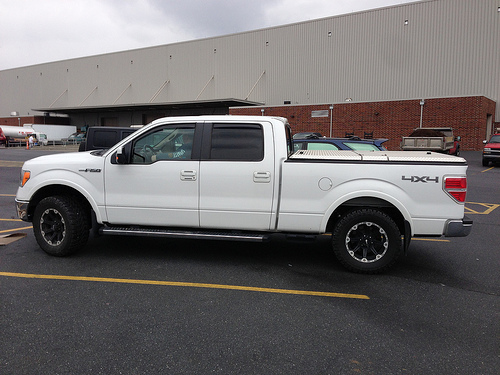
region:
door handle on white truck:
[173, 167, 204, 187]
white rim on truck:
[343, 220, 385, 263]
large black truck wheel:
[323, 203, 425, 293]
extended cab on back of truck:
[262, 107, 467, 189]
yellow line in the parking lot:
[62, 262, 403, 326]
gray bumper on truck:
[447, 215, 485, 242]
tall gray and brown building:
[175, 45, 407, 120]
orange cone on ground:
[21, 135, 30, 150]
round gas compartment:
[311, 173, 336, 195]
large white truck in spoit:
[24, 115, 465, 265]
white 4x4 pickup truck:
[1, 105, 483, 295]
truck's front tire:
[26, 184, 86, 261]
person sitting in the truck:
[136, 132, 196, 167]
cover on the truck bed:
[295, 143, 467, 175]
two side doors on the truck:
[102, 112, 276, 229]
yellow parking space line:
[7, 266, 377, 311]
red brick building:
[280, 100, 492, 150]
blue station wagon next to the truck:
[294, 135, 391, 152]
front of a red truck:
[479, 123, 499, 168]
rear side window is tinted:
[211, 123, 263, 163]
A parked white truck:
[12, 112, 477, 269]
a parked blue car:
[288, 132, 393, 150]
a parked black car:
[292, 129, 321, 142]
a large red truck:
[403, 125, 462, 154]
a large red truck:
[480, 133, 499, 168]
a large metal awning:
[31, 72, 267, 115]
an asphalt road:
[0, 142, 497, 374]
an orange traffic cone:
[23, 138, 30, 150]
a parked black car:
[76, 124, 141, 152]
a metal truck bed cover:
[290, 148, 465, 160]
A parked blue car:
[291, 133, 393, 152]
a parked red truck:
[400, 126, 460, 155]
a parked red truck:
[481, 131, 498, 163]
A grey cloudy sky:
[0, 0, 415, 75]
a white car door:
[101, 120, 203, 229]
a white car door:
[196, 120, 276, 232]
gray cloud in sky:
[0, 0, 405, 72]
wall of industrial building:
[3, 0, 495, 112]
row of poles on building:
[51, 68, 270, 107]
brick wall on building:
[229, 95, 494, 154]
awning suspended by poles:
[31, 96, 263, 116]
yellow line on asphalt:
[0, 270, 371, 301]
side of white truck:
[15, 114, 470, 271]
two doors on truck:
[104, 122, 274, 226]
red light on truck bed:
[443, 174, 467, 206]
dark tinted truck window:
[209, 124, 264, 161]